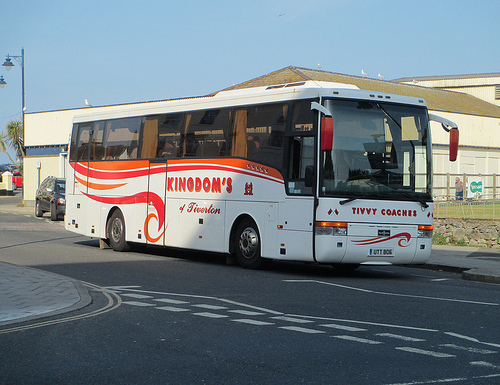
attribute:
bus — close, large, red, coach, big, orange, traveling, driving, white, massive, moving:
[79, 103, 449, 276]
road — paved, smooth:
[123, 255, 250, 357]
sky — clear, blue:
[143, 1, 260, 56]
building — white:
[23, 65, 499, 202]